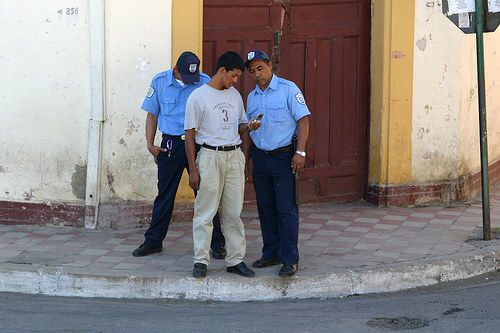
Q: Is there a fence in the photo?
A: No, there are no fences.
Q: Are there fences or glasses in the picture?
A: No, there are no fences or glasses.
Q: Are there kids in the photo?
A: No, there are no kids.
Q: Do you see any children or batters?
A: No, there are no children or batters.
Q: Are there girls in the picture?
A: No, there are no girls.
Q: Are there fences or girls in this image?
A: No, there are no girls or fences.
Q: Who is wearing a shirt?
A: The man is wearing a shirt.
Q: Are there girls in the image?
A: No, there are no girls.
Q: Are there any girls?
A: No, there are no girls.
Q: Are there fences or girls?
A: No, there are no girls or fences.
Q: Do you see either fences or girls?
A: No, there are no girls or fences.